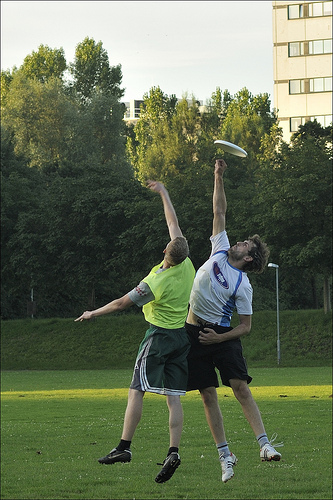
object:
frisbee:
[202, 125, 252, 179]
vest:
[144, 258, 196, 330]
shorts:
[126, 317, 192, 403]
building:
[264, 3, 332, 171]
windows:
[283, 35, 333, 61]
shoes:
[255, 426, 287, 470]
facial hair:
[231, 248, 247, 262]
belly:
[186, 299, 225, 323]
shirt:
[186, 224, 255, 330]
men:
[185, 124, 288, 492]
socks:
[115, 435, 134, 454]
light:
[0, 383, 333, 400]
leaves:
[64, 104, 74, 118]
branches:
[0, 33, 332, 263]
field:
[0, 360, 332, 497]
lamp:
[263, 258, 283, 274]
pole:
[273, 267, 283, 365]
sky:
[3, 5, 279, 107]